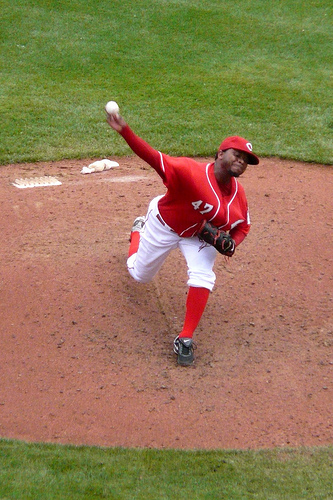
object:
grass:
[1, 0, 332, 166]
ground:
[1, 0, 333, 500]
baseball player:
[97, 112, 260, 367]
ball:
[105, 99, 119, 116]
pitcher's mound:
[1, 155, 333, 449]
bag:
[81, 158, 119, 174]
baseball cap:
[217, 134, 259, 166]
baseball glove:
[195, 219, 235, 257]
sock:
[177, 286, 211, 341]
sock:
[126, 230, 140, 259]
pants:
[125, 193, 220, 292]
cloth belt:
[156, 213, 177, 234]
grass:
[0, 436, 333, 499]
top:
[105, 100, 120, 107]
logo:
[182, 338, 191, 344]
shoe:
[171, 334, 197, 367]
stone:
[159, 383, 168, 390]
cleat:
[138, 215, 145, 228]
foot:
[128, 217, 146, 244]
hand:
[104, 104, 128, 132]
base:
[11, 174, 62, 188]